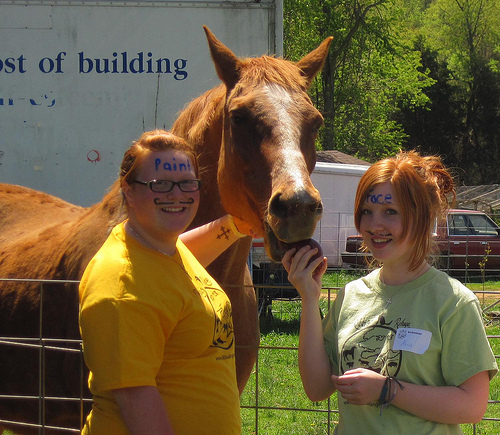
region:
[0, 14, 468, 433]
red hair, red hair, red horse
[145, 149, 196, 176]
i believe the word 'paint', painted in blue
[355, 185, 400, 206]
'face' i think, also painted in blue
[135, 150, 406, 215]
words painted on individual foreheads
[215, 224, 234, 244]
crucifix tattoo on inside wrist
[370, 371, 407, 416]
several braided bracelets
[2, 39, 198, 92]
".....st of building' also painted in blue on side of large truck, with more decayed, illegible print beneath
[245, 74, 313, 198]
thick cream stripe+star, or thin blaze on horses happy face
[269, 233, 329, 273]
a red apple a day, at least one, creates equine merriment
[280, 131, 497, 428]
Girl wearing a green shirt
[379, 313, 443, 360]
Tag on the girl's shirt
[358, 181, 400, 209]
Paint in the girl's face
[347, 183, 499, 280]
Car in the background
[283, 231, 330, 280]
Apple in the girl's hand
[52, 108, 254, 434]
Girl wearing a yellow shirt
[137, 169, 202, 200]
Glasses on the girl's face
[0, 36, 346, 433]
Horse behind the fence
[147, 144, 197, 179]
Paint on the girl's face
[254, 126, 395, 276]
Building in the background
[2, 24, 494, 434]
two women with a brown horse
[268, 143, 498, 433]
woman feeding an apple to horse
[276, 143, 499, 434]
woman holding an apple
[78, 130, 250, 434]
woman with painted mustache on face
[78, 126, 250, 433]
woman with paint on her forehead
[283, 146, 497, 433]
woman with red hair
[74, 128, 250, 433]
woman next to a horse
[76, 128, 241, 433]
woman wearing a yellow shirt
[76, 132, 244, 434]
woman wearing black glasses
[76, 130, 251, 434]
woman with tatoo on arm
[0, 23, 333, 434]
Brown horse standing in a field.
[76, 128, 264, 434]
Girl in yellow shirt petting a horse.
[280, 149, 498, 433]
Girl in green shirt feeding a horse.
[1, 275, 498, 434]
Fence to keep a horse inside field.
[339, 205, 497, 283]
Maroon car parked in the field.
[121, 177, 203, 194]
Glasses worn by girl in yellow shirt.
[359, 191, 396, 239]
Face paint on girl in green shirt.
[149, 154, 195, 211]
Face paint on girl in yellow shirt.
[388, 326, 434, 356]
Name tag on girl's green shirt.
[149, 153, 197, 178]
the writing on the woman's forehead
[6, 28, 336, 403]
a big reddish brown house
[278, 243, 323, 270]
the apple the horse is eating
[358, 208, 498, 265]
the car parked next to the fence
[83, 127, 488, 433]
two women standing by a happy horse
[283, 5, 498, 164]
some tall trees with many green leaves on them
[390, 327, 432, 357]
the nametag on the woman's shirt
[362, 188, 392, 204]
the writing on the other woman's face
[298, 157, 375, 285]
a white trailer parked by the truck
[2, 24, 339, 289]
brown horse standing behind fence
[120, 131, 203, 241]
red head woman wearing glasses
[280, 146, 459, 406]
red haired girl giving the horse an apple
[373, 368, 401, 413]
bracelet on girl's wrist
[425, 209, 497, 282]
red vehicle parked behind the fence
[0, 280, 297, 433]
metal fence made of squares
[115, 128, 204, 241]
girl wearing the word paint on forehead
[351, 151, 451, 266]
girl wearing a mustache painted on face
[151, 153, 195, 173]
the woman has lettering on her head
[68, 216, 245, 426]
the woman is wearing a t-shirt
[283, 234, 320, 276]
the woman is feeding the horse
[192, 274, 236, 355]
the woman's shirt has a graphic print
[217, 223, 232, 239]
the woman has a tattoo on her wrist